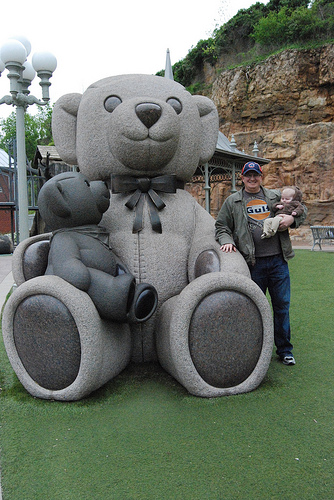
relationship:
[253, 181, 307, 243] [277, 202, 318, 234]
baby in arm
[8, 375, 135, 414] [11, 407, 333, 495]
dent in grass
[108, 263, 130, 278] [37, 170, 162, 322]
spot on bear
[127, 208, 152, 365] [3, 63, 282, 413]
center stitching on bear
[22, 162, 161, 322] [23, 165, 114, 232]
bear has upturned head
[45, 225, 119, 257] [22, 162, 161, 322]
neckerchief on bear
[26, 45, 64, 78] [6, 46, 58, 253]
bulb on post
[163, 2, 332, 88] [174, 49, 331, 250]
vegetation on top of mountain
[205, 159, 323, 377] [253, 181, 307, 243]
dad holds baby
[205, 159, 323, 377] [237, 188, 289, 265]
dad wears shirt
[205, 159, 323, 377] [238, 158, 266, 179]
dad wears cap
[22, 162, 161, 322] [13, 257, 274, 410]
bear in lap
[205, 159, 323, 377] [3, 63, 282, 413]
dad stands next to bear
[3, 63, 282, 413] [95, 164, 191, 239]
bear wears bow tie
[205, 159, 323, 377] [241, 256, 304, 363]
dad wears jeans